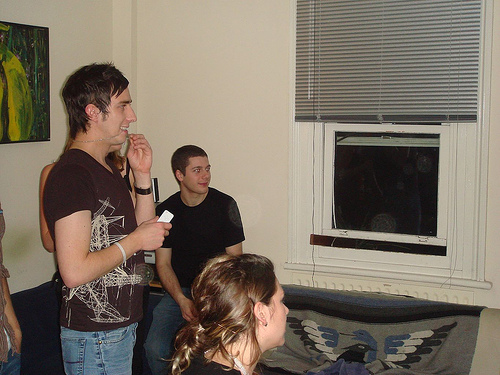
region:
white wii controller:
[152, 202, 179, 239]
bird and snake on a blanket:
[310, 311, 411, 372]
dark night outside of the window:
[352, 152, 398, 207]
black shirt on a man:
[160, 194, 240, 254]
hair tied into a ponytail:
[168, 297, 214, 372]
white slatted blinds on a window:
[315, 61, 445, 112]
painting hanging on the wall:
[0, 59, 64, 151]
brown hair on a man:
[59, 74, 115, 135]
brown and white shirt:
[87, 191, 152, 337]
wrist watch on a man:
[126, 180, 159, 207]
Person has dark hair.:
[70, 69, 125, 119]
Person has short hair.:
[62, 50, 117, 124]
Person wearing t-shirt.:
[53, 177, 146, 284]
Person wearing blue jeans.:
[45, 319, 140, 368]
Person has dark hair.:
[164, 130, 201, 175]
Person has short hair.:
[170, 139, 232, 181]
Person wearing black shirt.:
[181, 201, 236, 245]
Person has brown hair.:
[186, 269, 262, 341]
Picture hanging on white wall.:
[7, 27, 73, 163]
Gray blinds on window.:
[304, 37, 482, 133]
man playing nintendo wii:
[27, 51, 140, 373]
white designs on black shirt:
[65, 192, 140, 315]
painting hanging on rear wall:
[7, 21, 67, 141]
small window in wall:
[285, 122, 460, 272]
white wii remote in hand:
[140, 205, 200, 255]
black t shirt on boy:
[178, 193, 241, 280]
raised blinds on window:
[287, 4, 480, 119]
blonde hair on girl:
[167, 237, 315, 364]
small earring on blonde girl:
[251, 308, 275, 332]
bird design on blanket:
[282, 280, 442, 370]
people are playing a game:
[46, 36, 298, 365]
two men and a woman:
[50, 45, 277, 357]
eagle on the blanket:
[306, 313, 404, 367]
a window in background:
[289, 43, 486, 276]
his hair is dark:
[176, 128, 236, 219]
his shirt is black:
[162, 143, 245, 264]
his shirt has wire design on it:
[39, 166, 158, 304]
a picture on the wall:
[14, 30, 129, 197]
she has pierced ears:
[233, 277, 302, 363]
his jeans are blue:
[40, 300, 147, 370]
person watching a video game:
[39, 53, 177, 373]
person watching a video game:
[152, 245, 297, 374]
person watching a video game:
[130, 138, 249, 363]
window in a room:
[319, 128, 456, 248]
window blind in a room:
[284, 2, 496, 127]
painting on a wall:
[0, 15, 62, 154]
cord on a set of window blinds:
[300, 4, 320, 104]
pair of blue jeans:
[58, 311, 138, 373]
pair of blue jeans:
[139, 288, 196, 374]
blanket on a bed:
[253, 283, 496, 373]